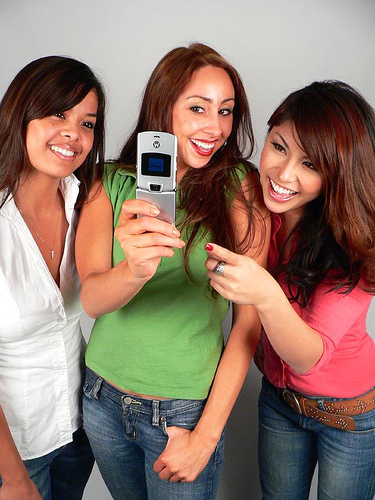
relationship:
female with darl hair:
[203, 80, 375, 500] [266, 78, 375, 310]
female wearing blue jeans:
[0, 55, 106, 500] [20, 427, 97, 499]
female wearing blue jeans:
[74, 42, 271, 500] [82, 367, 225, 499]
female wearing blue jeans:
[203, 80, 375, 500] [256, 375, 375, 499]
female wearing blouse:
[0, 55, 106, 500] [0, 175, 85, 460]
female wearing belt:
[203, 80, 375, 500] [262, 374, 373, 430]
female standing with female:
[203, 80, 373, 498] [74, 42, 270, 498]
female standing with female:
[74, 42, 270, 498] [0, 55, 105, 499]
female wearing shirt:
[203, 80, 375, 500] [252, 204, 363, 402]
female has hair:
[74, 42, 271, 500] [113, 43, 269, 302]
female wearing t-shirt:
[74, 42, 271, 500] [78, 152, 258, 403]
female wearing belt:
[74, 42, 271, 500] [274, 385, 372, 432]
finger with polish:
[193, 236, 242, 264] [204, 243, 214, 250]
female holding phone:
[74, 42, 271, 500] [129, 39, 241, 223]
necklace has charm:
[11, 199, 62, 262] [50, 248, 54, 259]